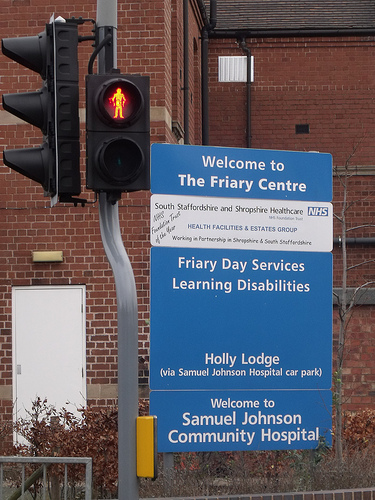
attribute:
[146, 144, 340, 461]
sign — english language, white, blue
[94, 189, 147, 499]
pole — metal, gray, silver, grey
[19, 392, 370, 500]
bushes — red, brown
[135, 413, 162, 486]
box — yellow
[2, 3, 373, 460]
building — brick, red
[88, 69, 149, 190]
traffic light — black, crosswalk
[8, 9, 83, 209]
traffic light — black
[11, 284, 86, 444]
door — white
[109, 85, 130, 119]
person outline — yellow, orange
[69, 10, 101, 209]
pipes — black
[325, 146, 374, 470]
tree — leafless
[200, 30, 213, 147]
rain gutter — metal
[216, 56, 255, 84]
vent — white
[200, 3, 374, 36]
roof — gray, tiled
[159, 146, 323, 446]
lettering — white